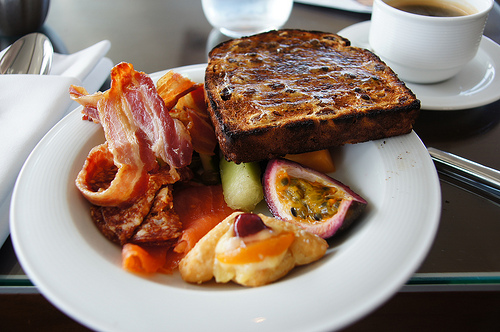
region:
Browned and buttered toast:
[169, 1, 478, 206]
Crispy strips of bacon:
[46, 42, 227, 249]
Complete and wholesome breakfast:
[35, 3, 470, 308]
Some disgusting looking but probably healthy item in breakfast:
[241, 140, 388, 274]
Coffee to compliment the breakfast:
[322, 2, 497, 106]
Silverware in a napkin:
[3, 2, 148, 326]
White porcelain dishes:
[21, 2, 481, 328]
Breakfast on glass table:
[4, 144, 487, 319]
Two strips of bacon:
[30, 58, 235, 231]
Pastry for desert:
[170, 197, 352, 302]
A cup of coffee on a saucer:
[338, 2, 490, 88]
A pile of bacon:
[75, 62, 195, 182]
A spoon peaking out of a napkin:
[0, 20, 95, 80]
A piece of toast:
[198, 34, 407, 140]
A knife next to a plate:
[428, 137, 498, 183]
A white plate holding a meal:
[24, 89, 436, 320]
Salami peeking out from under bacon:
[81, 162, 195, 253]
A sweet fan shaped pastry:
[184, 205, 328, 283]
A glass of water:
[193, 1, 294, 35]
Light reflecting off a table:
[46, 3, 129, 43]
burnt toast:
[183, 19, 430, 152]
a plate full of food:
[70, 58, 392, 318]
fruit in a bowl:
[231, 151, 395, 268]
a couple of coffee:
[378, 0, 485, 134]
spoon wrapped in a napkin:
[1, 25, 71, 93]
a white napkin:
[0, 23, 122, 185]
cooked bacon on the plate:
[61, 48, 210, 216]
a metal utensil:
[403, 133, 498, 196]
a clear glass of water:
[189, 1, 327, 61]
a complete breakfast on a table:
[16, 9, 488, 312]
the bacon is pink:
[51, 59, 218, 236]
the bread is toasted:
[172, 29, 447, 177]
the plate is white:
[28, 50, 468, 330]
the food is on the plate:
[94, 33, 409, 308]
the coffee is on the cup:
[373, 4, 498, 97]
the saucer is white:
[336, 15, 494, 142]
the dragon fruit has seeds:
[267, 156, 359, 235]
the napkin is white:
[16, 32, 91, 153]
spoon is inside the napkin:
[1, 32, 103, 219]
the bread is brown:
[192, 20, 412, 216]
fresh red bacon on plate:
[86, 117, 166, 189]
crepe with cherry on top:
[223, 224, 302, 272]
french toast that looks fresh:
[228, 107, 383, 161]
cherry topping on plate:
[229, 216, 279, 247]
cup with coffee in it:
[367, 12, 459, 96]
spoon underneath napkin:
[1, 27, 41, 89]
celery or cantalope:
[221, 163, 273, 215]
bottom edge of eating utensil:
[436, 141, 473, 196]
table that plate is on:
[453, 228, 491, 299]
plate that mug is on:
[426, 73, 479, 113]